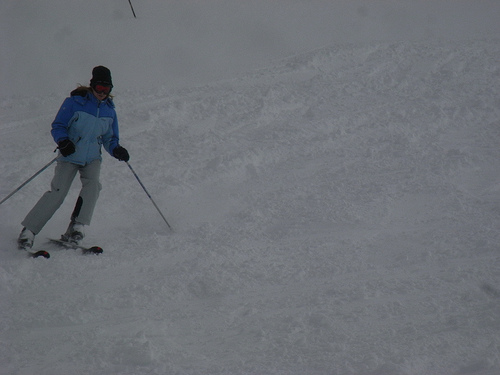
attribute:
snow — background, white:
[1, 0, 498, 374]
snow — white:
[248, 89, 430, 313]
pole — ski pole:
[1, 140, 71, 216]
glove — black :
[109, 145, 130, 162]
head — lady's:
[82, 51, 137, 103]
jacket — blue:
[49, 87, 124, 181]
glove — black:
[113, 143, 130, 160]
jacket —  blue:
[49, 87, 121, 163]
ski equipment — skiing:
[23, 244, 51, 261]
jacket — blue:
[40, 85, 124, 166]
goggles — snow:
[92, 85, 113, 93]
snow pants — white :
[16, 163, 106, 270]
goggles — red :
[92, 77, 114, 97]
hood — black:
[70, 81, 95, 98]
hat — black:
[83, 60, 116, 94]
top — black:
[30, 243, 109, 258]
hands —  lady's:
[59, 135, 134, 177]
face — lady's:
[91, 76, 115, 95]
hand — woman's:
[54, 134, 130, 165]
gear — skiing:
[3, 141, 168, 247]